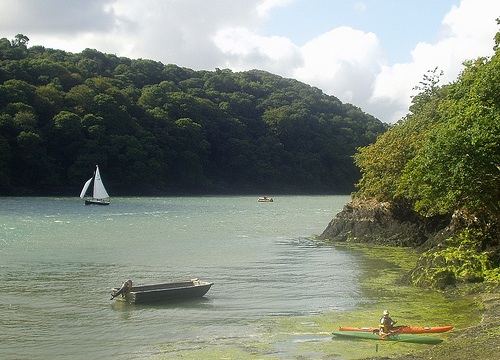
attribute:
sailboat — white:
[79, 163, 110, 209]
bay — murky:
[2, 196, 477, 358]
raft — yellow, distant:
[258, 197, 276, 205]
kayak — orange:
[335, 323, 453, 345]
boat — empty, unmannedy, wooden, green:
[108, 276, 216, 303]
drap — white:
[92, 164, 113, 203]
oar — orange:
[381, 320, 398, 339]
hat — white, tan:
[382, 307, 391, 317]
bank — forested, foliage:
[3, 153, 362, 198]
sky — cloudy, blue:
[1, 1, 497, 122]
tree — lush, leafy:
[47, 109, 93, 183]